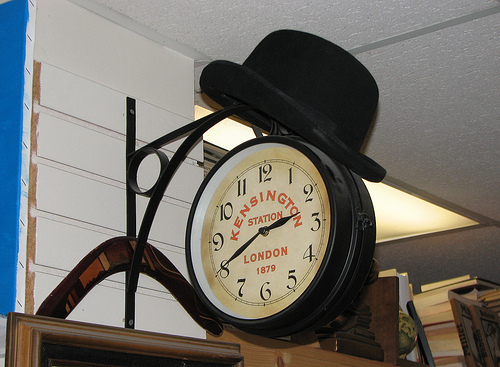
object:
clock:
[180, 132, 378, 349]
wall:
[15, 1, 219, 363]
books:
[398, 271, 499, 367]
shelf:
[361, 262, 499, 364]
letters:
[226, 190, 308, 275]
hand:
[266, 209, 300, 230]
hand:
[210, 232, 260, 275]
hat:
[194, 23, 392, 187]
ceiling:
[47, 0, 499, 229]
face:
[187, 139, 333, 322]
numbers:
[203, 155, 326, 306]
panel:
[30, 216, 198, 304]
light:
[188, 103, 492, 253]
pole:
[118, 93, 156, 332]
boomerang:
[30, 230, 232, 342]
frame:
[8, 311, 245, 366]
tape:
[1, 3, 41, 319]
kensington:
[229, 189, 306, 242]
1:
[287, 166, 294, 190]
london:
[237, 242, 294, 271]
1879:
[252, 263, 281, 275]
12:
[258, 164, 273, 184]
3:
[307, 209, 325, 233]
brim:
[200, 59, 386, 182]